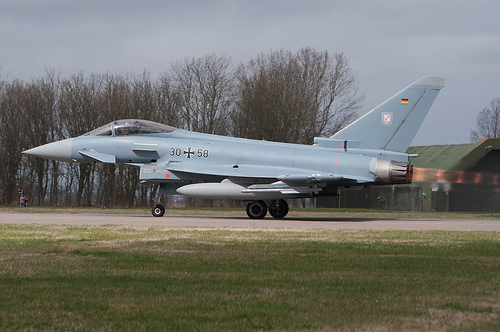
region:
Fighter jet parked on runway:
[20, 75, 447, 220]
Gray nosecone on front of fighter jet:
[20, 136, 75, 163]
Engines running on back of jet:
[386, 160, 499, 185]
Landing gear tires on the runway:
[151, 198, 290, 220]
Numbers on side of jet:
[168, 145, 209, 159]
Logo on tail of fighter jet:
[381, 111, 393, 125]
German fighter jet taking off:
[21, 69, 450, 219]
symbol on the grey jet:
[182, 144, 197, 161]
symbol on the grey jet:
[397, 95, 412, 104]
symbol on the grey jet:
[380, 111, 394, 129]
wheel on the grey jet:
[149, 198, 166, 217]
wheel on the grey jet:
[242, 196, 267, 219]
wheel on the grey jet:
[267, 197, 290, 221]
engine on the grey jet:
[340, 148, 415, 187]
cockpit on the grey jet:
[90, 117, 171, 134]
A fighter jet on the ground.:
[19, 73, 446, 218]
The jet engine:
[365, 150, 498, 192]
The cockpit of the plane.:
[81, 114, 176, 139]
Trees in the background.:
[0, 41, 372, 121]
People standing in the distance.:
[15, 190, 30, 207]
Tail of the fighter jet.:
[314, 72, 449, 152]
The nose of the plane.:
[21, 135, 73, 158]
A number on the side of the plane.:
[164, 144, 209, 161]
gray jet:
[37, 72, 447, 196]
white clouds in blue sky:
[360, 19, 402, 43]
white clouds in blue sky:
[414, 33, 461, 51]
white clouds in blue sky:
[47, 9, 101, 44]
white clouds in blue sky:
[335, 8, 400, 42]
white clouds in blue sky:
[442, 1, 493, 58]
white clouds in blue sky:
[241, 9, 301, 37]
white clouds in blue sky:
[124, 18, 195, 53]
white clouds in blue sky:
[52, 11, 133, 51]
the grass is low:
[326, 258, 407, 301]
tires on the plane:
[242, 198, 292, 221]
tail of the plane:
[363, 83, 445, 160]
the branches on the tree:
[244, 61, 322, 122]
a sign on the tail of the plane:
[383, 112, 392, 126]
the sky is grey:
[126, 23, 185, 40]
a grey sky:
[370, 24, 420, 59]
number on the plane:
[168, 140, 185, 158]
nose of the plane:
[18, 144, 43, 160]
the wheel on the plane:
[151, 200, 166, 215]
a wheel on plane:
[271, 200, 292, 220]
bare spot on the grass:
[0, 223, 247, 244]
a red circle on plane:
[156, 169, 176, 181]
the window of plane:
[91, 115, 180, 141]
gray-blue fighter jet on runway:
[20, 71, 447, 219]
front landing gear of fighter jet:
[150, 183, 167, 218]